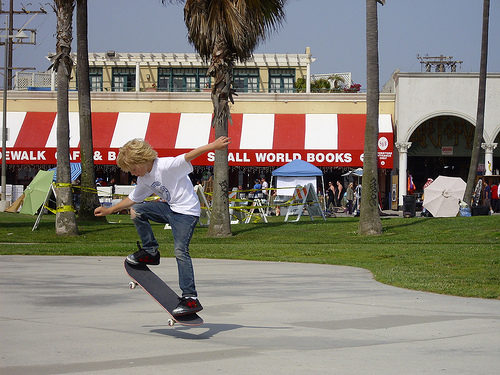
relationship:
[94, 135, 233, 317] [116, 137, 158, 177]
boy with blonde hair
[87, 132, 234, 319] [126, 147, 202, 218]
boy wearing shirt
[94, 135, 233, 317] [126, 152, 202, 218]
boy wearing shirt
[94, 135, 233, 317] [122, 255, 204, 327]
boy using skateboard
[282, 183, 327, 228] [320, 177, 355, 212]
warning sign for people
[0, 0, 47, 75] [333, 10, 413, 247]
gadgets on pole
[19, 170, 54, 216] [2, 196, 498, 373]
parasol laying on ground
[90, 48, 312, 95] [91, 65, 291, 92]
building with windows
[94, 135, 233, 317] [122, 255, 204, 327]
boy on skateboard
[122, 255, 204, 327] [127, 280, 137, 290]
skateboard with wheel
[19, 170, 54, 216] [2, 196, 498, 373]
parasol on ground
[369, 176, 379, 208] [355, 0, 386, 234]
graffiti on tree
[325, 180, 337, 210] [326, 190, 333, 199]
woman in shirt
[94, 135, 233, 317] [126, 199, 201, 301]
boy wearing jeans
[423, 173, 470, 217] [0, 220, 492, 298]
parasol on grass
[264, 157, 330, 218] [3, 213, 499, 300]
canopy on grass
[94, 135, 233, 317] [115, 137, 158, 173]
boy with blonde hair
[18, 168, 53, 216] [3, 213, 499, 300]
parasol on grass